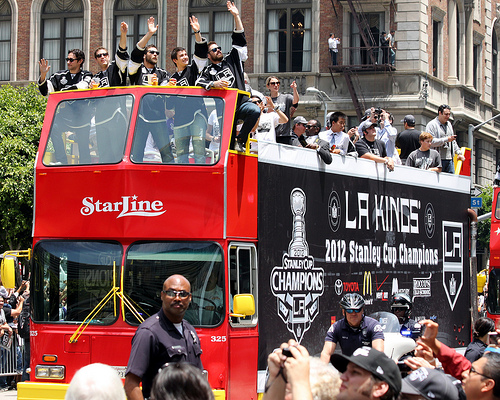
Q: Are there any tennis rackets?
A: No, there are no tennis rackets.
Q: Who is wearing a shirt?
A: The man is wearing a shirt.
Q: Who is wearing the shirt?
A: The man is wearing a shirt.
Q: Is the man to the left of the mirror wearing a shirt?
A: Yes, the man is wearing a shirt.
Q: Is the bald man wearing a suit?
A: No, the man is wearing a shirt.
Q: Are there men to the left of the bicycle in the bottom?
A: Yes, there is a man to the left of the bicycle.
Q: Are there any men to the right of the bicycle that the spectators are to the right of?
A: No, the man is to the left of the bicycle.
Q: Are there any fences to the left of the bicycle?
A: No, there is a man to the left of the bicycle.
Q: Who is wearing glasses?
A: The man is wearing glasses.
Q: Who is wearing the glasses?
A: The man is wearing glasses.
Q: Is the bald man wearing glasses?
A: Yes, the man is wearing glasses.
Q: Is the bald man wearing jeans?
A: No, the man is wearing glasses.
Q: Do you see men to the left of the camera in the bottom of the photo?
A: Yes, there is a man to the left of the camera.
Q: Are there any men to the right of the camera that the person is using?
A: No, the man is to the left of the camera.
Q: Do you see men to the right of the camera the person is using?
A: No, the man is to the left of the camera.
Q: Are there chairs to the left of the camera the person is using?
A: No, there is a man to the left of the camera.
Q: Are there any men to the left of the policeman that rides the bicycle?
A: Yes, there is a man to the left of the police officer.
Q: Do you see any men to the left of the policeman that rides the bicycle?
A: Yes, there is a man to the left of the police officer.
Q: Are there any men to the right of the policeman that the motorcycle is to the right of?
A: No, the man is to the left of the policeman.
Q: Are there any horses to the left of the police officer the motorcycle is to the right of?
A: No, there is a man to the left of the police officer.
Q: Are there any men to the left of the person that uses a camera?
A: Yes, there is a man to the left of the person.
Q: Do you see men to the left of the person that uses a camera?
A: Yes, there is a man to the left of the person.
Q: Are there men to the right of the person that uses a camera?
A: No, the man is to the left of the person.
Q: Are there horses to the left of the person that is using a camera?
A: No, there is a man to the left of the person.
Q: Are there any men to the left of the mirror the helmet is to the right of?
A: Yes, there is a man to the left of the mirror.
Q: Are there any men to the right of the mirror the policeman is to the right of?
A: No, the man is to the left of the mirror.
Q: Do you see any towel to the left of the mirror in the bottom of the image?
A: No, there is a man to the left of the mirror.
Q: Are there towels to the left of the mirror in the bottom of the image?
A: No, there is a man to the left of the mirror.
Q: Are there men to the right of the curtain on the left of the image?
A: Yes, there is a man to the right of the curtain.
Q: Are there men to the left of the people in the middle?
A: Yes, there is a man to the left of the people.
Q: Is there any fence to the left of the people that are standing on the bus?
A: No, there is a man to the left of the people.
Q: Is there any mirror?
A: Yes, there is a mirror.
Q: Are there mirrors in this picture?
A: Yes, there is a mirror.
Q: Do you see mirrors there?
A: Yes, there is a mirror.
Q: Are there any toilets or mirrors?
A: Yes, there is a mirror.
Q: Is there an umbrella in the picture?
A: No, there are no umbrellas.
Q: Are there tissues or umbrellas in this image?
A: No, there are no umbrellas or tissues.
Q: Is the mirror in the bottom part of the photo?
A: Yes, the mirror is in the bottom of the image.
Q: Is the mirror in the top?
A: No, the mirror is in the bottom of the image.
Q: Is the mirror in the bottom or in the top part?
A: The mirror is in the bottom of the image.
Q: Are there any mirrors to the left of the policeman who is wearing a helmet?
A: Yes, there is a mirror to the left of the policeman.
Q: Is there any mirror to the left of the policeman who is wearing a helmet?
A: Yes, there is a mirror to the left of the policeman.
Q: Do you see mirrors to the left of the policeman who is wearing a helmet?
A: Yes, there is a mirror to the left of the policeman.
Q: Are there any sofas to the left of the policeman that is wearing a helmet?
A: No, there is a mirror to the left of the policeman.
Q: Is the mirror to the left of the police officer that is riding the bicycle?
A: Yes, the mirror is to the left of the policeman.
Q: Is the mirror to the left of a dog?
A: No, the mirror is to the left of the policeman.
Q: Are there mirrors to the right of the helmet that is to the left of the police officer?
A: No, the mirror is to the left of the helmet.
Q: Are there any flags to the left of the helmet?
A: No, there is a mirror to the left of the helmet.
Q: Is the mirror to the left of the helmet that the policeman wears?
A: Yes, the mirror is to the left of the helmet.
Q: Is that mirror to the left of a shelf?
A: No, the mirror is to the left of the helmet.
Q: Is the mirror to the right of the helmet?
A: No, the mirror is to the left of the helmet.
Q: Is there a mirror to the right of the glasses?
A: Yes, there is a mirror to the right of the glasses.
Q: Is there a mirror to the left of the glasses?
A: No, the mirror is to the right of the glasses.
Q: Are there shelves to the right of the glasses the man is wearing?
A: No, there is a mirror to the right of the glasses.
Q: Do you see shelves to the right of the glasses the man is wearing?
A: No, there is a mirror to the right of the glasses.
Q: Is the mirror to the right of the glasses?
A: Yes, the mirror is to the right of the glasses.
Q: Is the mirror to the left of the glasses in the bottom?
A: No, the mirror is to the right of the glasses.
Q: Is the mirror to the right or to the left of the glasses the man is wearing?
A: The mirror is to the right of the glasses.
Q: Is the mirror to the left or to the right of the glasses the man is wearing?
A: The mirror is to the right of the glasses.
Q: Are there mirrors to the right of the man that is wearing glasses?
A: Yes, there is a mirror to the right of the man.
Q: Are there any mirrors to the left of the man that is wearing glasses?
A: No, the mirror is to the right of the man.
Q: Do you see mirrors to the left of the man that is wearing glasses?
A: No, the mirror is to the right of the man.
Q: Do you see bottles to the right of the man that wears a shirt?
A: No, there is a mirror to the right of the man.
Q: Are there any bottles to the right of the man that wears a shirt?
A: No, there is a mirror to the right of the man.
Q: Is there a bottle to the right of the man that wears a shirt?
A: No, there is a mirror to the right of the man.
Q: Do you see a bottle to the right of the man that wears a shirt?
A: No, there is a mirror to the right of the man.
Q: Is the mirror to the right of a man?
A: Yes, the mirror is to the right of a man.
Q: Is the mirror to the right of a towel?
A: No, the mirror is to the right of a man.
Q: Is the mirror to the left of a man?
A: No, the mirror is to the right of a man.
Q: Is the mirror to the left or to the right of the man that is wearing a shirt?
A: The mirror is to the right of the man.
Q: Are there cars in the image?
A: No, there are no cars.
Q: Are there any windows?
A: Yes, there is a window.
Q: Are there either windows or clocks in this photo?
A: Yes, there is a window.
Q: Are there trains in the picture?
A: No, there are no trains.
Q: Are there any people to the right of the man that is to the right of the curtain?
A: Yes, there are people to the right of the man.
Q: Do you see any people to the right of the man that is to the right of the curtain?
A: Yes, there are people to the right of the man.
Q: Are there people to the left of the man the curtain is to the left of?
A: No, the people are to the right of the man.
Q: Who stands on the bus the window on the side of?
A: The people stand on the bus.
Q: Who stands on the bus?
A: The people stand on the bus.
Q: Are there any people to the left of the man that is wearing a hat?
A: Yes, there are people to the left of the man.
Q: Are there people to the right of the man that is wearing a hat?
A: No, the people are to the left of the man.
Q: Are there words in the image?
A: Yes, there are words.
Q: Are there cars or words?
A: Yes, there are words.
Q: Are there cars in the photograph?
A: No, there are no cars.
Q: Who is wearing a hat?
A: The man is wearing a hat.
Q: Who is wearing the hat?
A: The man is wearing a hat.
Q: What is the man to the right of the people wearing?
A: The man is wearing a hat.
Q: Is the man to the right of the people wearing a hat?
A: Yes, the man is wearing a hat.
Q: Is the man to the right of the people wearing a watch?
A: No, the man is wearing a hat.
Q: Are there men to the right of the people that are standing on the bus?
A: Yes, there is a man to the right of the people.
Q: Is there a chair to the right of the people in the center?
A: No, there is a man to the right of the people.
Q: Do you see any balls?
A: No, there are no balls.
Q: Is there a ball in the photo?
A: No, there are no balls.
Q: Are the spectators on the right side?
A: Yes, the spectators are on the right of the image.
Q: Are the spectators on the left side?
A: No, the spectators are on the right of the image.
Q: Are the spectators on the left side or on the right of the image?
A: The spectators are on the right of the image.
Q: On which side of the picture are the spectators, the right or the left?
A: The spectators are on the right of the image.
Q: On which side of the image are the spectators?
A: The spectators are on the right of the image.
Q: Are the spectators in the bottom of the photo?
A: Yes, the spectators are in the bottom of the image.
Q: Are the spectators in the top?
A: No, the spectators are in the bottom of the image.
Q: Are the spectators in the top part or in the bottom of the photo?
A: The spectators are in the bottom of the image.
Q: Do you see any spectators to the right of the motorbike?
A: Yes, there are spectators to the right of the motorbike.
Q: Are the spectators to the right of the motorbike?
A: Yes, the spectators are to the right of the motorbike.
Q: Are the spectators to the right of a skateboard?
A: No, the spectators are to the right of the motorbike.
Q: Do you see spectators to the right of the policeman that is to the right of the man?
A: Yes, there are spectators to the right of the policeman.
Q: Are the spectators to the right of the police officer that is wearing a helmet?
A: Yes, the spectators are to the right of the policeman.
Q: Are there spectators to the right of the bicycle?
A: Yes, there are spectators to the right of the bicycle.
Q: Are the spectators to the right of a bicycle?
A: Yes, the spectators are to the right of a bicycle.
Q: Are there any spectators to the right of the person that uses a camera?
A: Yes, there are spectators to the right of the person.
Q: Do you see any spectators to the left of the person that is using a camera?
A: No, the spectators are to the right of the person.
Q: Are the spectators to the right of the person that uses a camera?
A: Yes, the spectators are to the right of the person.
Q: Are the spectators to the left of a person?
A: No, the spectators are to the right of a person.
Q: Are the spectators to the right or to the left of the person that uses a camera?
A: The spectators are to the right of the person.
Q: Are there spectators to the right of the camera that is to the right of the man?
A: Yes, there are spectators to the right of the camera.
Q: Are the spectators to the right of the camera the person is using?
A: Yes, the spectators are to the right of the camera.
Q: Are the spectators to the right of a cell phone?
A: No, the spectators are to the right of the camera.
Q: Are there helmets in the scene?
A: Yes, there is a helmet.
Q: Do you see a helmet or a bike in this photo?
A: Yes, there is a helmet.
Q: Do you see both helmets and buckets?
A: No, there is a helmet but no buckets.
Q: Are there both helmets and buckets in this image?
A: No, there is a helmet but no buckets.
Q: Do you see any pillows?
A: No, there are no pillows.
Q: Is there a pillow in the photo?
A: No, there are no pillows.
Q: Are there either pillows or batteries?
A: No, there are no pillows or batteries.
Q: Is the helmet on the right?
A: Yes, the helmet is on the right of the image.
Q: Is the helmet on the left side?
A: No, the helmet is on the right of the image.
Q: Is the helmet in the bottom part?
A: Yes, the helmet is in the bottom of the image.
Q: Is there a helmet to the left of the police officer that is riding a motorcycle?
A: Yes, there is a helmet to the left of the policeman.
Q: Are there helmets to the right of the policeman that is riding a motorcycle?
A: No, the helmet is to the left of the police officer.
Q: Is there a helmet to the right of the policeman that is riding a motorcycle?
A: No, the helmet is to the left of the police officer.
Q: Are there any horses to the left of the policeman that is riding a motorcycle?
A: No, there is a helmet to the left of the police officer.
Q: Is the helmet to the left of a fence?
A: No, the helmet is to the left of a policeman.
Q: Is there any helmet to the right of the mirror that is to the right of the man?
A: Yes, there is a helmet to the right of the mirror.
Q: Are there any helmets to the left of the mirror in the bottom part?
A: No, the helmet is to the right of the mirror.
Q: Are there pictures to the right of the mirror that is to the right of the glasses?
A: No, there is a helmet to the right of the mirror.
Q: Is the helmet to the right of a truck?
A: No, the helmet is to the right of the mirror.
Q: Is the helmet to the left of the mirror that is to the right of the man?
A: No, the helmet is to the right of the mirror.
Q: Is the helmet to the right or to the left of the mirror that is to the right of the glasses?
A: The helmet is to the right of the mirror.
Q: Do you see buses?
A: Yes, there is a bus.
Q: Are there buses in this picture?
A: Yes, there is a bus.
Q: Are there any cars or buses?
A: Yes, there is a bus.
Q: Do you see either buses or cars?
A: Yes, there is a bus.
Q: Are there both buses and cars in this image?
A: No, there is a bus but no cars.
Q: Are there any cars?
A: No, there are no cars.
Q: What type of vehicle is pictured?
A: The vehicle is a bus.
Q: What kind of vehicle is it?
A: The vehicle is a bus.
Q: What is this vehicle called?
A: This is a bus.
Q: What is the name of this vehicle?
A: This is a bus.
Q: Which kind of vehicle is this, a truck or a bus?
A: This is a bus.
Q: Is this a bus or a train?
A: This is a bus.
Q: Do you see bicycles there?
A: Yes, there is a bicycle.